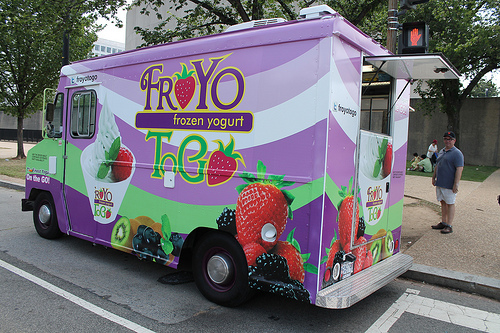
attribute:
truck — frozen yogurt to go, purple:
[20, 12, 462, 311]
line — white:
[0, 259, 154, 332]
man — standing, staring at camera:
[433, 131, 463, 235]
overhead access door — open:
[365, 54, 458, 81]